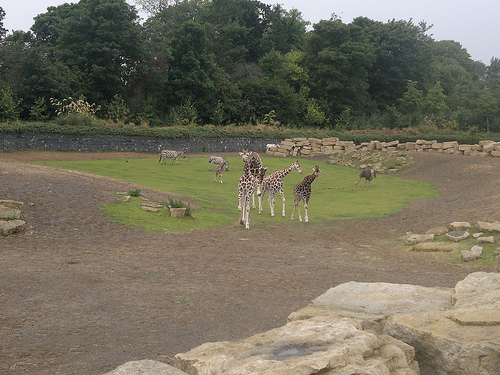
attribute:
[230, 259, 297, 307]
ground — dry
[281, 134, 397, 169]
boulders — large, gray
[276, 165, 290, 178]
neck — long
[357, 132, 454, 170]
stone blocks — big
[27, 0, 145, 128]
tree — green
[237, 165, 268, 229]
giraffe — herded, brown, walking, white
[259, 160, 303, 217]
giraffe — herded, brown, walking, white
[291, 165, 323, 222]
giraffe — herded, brown, walking, white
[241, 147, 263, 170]
giraffe — herded, brown, walking, white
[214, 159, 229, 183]
giraffe — herded, brown, walking, white, baby, small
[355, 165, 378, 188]
gazelle — grey, running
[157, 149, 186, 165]
zebra — black, walking, white, eating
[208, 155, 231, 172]
zebra — black, walking, white, grazing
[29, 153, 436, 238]
grass — green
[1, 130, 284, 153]
wall — brick, stone, bordering, dark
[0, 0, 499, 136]
trees — green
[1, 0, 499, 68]
sky — clear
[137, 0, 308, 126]
tree — green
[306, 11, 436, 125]
tree — green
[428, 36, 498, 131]
tree — green